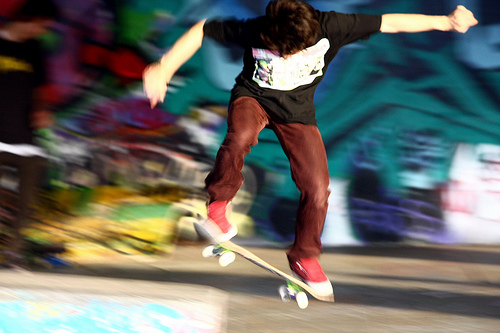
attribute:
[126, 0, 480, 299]
man — looking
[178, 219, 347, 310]
skateboard — slanted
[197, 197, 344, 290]
shoes — red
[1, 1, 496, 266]
background — blurry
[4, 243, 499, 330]
ground — shadowy